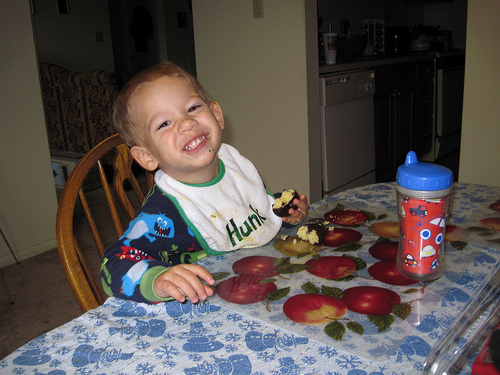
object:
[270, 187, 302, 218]
food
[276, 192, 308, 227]
hand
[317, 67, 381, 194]
machine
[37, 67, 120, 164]
couch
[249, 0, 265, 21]
light switch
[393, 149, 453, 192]
lid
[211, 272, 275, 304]
apple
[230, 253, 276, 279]
apple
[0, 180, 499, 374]
table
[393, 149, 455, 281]
cup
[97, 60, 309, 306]
baby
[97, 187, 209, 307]
pajamas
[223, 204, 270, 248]
hunk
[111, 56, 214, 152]
hair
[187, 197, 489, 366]
place mat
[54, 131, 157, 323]
chair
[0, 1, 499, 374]
kitchen scene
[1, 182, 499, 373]
cloth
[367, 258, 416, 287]
apple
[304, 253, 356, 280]
apple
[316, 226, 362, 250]
apple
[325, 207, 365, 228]
apple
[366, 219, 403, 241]
apple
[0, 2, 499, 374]
camera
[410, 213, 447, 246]
car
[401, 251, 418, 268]
car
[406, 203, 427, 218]
car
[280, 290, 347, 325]
apple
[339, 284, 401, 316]
apple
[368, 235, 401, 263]
apple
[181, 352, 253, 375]
snowman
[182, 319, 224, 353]
snowman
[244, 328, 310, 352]
snowman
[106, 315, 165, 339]
snowman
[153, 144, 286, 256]
baby bib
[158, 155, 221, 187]
boy's neck